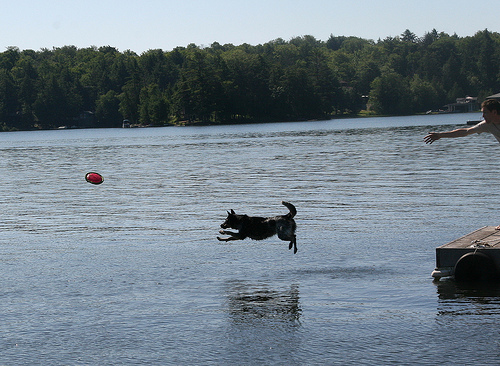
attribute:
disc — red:
[84, 169, 106, 187]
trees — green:
[2, 27, 497, 129]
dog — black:
[207, 206, 321, 253]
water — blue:
[1, 112, 498, 364]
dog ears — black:
[219, 209, 244, 228]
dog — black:
[219, 202, 321, 257]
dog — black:
[216, 196, 297, 255]